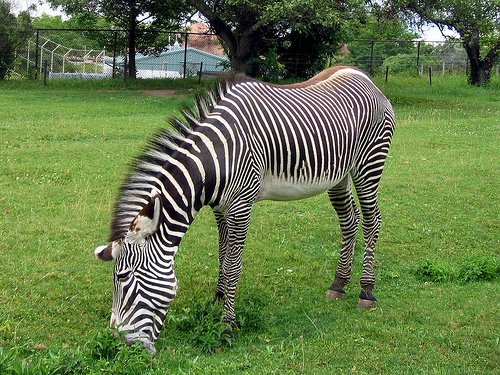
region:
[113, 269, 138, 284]
the zebra has an eye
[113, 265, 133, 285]
the eye is dark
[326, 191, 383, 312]
the zebra has back legs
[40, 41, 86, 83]
the fence is high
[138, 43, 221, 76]
the building is green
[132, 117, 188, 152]
the zebra has a mane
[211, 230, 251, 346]
the zebra has front legs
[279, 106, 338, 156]
the zebra has stripes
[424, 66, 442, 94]
the post is wooden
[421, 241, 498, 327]
patch of green grass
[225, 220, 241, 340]
left front leg on zebra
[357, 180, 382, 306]
left rear leg on zebra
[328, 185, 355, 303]
right rear leg on zebra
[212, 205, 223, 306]
right front leg on zebra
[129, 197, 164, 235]
left ear of the zebra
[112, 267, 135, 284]
left eye on the zebra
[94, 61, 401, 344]
zebra grazing in the grass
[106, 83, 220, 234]
mane on the neck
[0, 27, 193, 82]
black fence around the zebra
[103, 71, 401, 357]
the zebra is white and black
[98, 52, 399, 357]
the zebra has stripes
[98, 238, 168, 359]
the zebras is grazing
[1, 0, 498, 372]
scene takes place outdoors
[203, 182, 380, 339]
the zebra has four legs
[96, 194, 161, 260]
the zebra has ears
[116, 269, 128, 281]
the zebra has black eyes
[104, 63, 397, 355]
the zebra is standing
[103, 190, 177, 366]
the zebra is eating grass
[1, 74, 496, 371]
the grass is bright green and short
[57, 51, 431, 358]
a zebra eating grass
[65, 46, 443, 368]
a black and white zebra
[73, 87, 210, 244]
mane of zebra on neck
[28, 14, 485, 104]
a black fence line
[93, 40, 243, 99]
a large blue building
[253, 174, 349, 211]
a white underbelly on zebra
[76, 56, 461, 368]
a white zebra with black stripes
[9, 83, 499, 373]
grass covers the ground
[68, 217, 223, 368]
large head of zebra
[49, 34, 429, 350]
a zebra standing by himself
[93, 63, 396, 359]
Large black and white stiped zebra.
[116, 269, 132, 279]
A thin black eye of a zebra.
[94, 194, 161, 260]
A brown, black and white set of ears on a zebra.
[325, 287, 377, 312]
Two back grey hooves on a zebra.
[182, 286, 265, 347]
A green patch of grass around a zebras front hooves.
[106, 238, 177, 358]
A large black and white head of a zebra.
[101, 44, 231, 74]
A blue pitched roof and building.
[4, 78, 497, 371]
A green grassy field.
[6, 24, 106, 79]
A higher grey chain linked fence by a building.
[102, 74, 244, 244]
A black and white mane of a zebra.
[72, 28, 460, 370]
this is a zebra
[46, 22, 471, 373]
the zebra is alone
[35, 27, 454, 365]
the zebra is in a field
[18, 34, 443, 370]
the zebra is striped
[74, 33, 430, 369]
the zebra is eating grass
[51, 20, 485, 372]
the zebra is eating the green grass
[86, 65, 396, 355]
Black and white zebra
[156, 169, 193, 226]
Black stripe on the zebra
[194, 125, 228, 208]
Black stripe on the zebra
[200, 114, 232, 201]
Black stripe on the zebra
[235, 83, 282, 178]
Black stripe on the zebra